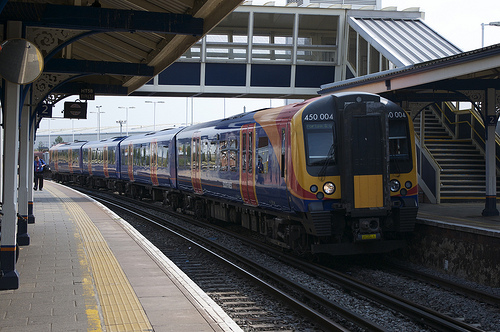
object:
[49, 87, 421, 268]
train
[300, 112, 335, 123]
number 450 004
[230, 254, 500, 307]
rail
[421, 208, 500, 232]
line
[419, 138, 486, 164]
stair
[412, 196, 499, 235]
platform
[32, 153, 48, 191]
man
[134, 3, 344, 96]
catwalk platform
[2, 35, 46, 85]
mirror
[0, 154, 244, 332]
platform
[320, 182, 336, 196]
light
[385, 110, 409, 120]
number print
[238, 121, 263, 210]
door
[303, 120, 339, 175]
windshield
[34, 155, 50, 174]
shirt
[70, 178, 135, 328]
stripe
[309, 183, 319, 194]
right headlight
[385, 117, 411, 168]
windshield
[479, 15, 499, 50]
light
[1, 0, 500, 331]
train station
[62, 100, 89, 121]
sign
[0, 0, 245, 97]
ceiling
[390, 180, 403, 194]
headlight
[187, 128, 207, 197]
door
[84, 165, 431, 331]
train track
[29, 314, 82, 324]
brick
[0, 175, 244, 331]
ground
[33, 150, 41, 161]
head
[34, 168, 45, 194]
pants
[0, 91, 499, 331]
foreground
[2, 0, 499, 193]
background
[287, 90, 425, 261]
end part